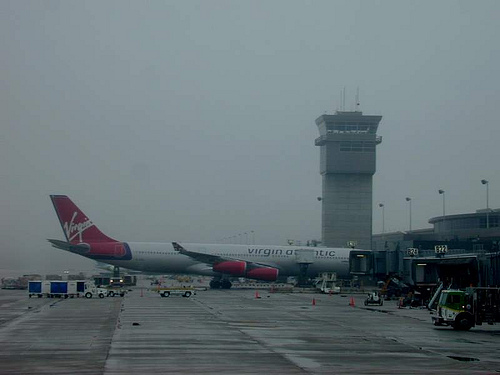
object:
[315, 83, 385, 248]
tower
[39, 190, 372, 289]
plane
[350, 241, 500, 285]
terminal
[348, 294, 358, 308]
cone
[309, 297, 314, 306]
cone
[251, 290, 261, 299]
cone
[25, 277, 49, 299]
truck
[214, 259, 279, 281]
engine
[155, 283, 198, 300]
vehicle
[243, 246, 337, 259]
sign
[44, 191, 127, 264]
tail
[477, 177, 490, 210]
lights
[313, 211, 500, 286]
building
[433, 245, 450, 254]
numbers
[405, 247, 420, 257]
numbers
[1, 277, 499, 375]
ground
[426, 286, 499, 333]
truck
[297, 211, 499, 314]
airport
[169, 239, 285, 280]
wing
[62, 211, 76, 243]
lettering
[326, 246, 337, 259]
lettering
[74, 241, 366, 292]
side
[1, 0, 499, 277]
overcast